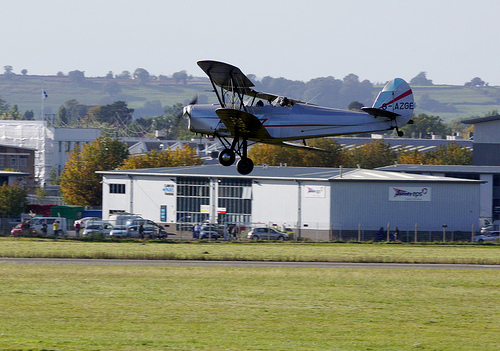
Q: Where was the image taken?
A: It was taken at the field.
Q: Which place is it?
A: It is a field.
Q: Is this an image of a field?
A: Yes, it is showing a field.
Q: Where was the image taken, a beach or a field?
A: It was taken at a field.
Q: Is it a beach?
A: No, it is a field.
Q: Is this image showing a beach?
A: No, the picture is showing a field.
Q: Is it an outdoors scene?
A: Yes, it is outdoors.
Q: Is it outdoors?
A: Yes, it is outdoors.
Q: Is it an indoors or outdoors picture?
A: It is outdoors.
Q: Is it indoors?
A: No, it is outdoors.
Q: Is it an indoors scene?
A: No, it is outdoors.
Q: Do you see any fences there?
A: Yes, there is a fence.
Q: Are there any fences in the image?
A: Yes, there is a fence.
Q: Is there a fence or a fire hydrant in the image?
A: Yes, there is a fence.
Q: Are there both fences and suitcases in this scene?
A: No, there is a fence but no suitcases.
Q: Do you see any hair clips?
A: No, there are no hair clips.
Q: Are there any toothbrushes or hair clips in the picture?
A: No, there are no hair clips or toothbrushes.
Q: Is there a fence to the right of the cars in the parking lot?
A: Yes, there is a fence to the right of the cars.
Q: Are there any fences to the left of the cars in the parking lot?
A: No, the fence is to the right of the cars.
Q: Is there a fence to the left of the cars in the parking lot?
A: No, the fence is to the right of the cars.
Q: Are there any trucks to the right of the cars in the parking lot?
A: No, there is a fence to the right of the cars.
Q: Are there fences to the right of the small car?
A: Yes, there is a fence to the right of the car.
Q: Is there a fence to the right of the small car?
A: Yes, there is a fence to the right of the car.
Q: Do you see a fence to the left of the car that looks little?
A: No, the fence is to the right of the car.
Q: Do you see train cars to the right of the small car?
A: No, there is a fence to the right of the car.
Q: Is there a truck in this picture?
A: No, there are no trucks.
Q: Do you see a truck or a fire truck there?
A: No, there are no trucks or fire trucks.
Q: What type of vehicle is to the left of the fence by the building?
A: The vehicle is a car.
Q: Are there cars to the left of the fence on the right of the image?
A: Yes, there is a car to the left of the fence.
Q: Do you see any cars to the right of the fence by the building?
A: No, the car is to the left of the fence.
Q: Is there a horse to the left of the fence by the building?
A: No, there is a car to the left of the fence.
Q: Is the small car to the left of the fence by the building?
A: Yes, the car is to the left of the fence.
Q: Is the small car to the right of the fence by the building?
A: No, the car is to the left of the fence.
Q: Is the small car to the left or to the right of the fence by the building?
A: The car is to the left of the fence.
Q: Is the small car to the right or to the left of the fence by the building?
A: The car is to the left of the fence.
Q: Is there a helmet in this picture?
A: No, there are no helmets.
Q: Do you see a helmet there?
A: No, there are no helmets.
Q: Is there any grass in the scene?
A: Yes, there is grass.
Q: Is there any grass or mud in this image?
A: Yes, there is grass.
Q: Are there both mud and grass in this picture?
A: No, there is grass but no mud.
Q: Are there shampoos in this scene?
A: No, there are no shampoos.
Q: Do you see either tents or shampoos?
A: No, there are no shampoos or tents.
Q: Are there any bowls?
A: No, there are no bowls.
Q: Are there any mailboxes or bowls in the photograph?
A: No, there are no bowls or mailboxes.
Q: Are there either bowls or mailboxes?
A: No, there are no bowls or mailboxes.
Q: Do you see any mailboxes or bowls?
A: No, there are no bowls or mailboxes.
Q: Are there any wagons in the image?
A: No, there are no wagons.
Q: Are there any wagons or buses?
A: No, there are no wagons or buses.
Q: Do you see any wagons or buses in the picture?
A: No, there are no wagons or buses.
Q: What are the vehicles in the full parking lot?
A: The vehicles are cars.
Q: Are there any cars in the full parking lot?
A: Yes, there are cars in the parking lot.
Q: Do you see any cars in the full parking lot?
A: Yes, there are cars in the parking lot.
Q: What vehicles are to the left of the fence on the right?
A: The vehicles are cars.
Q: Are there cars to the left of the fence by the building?
A: Yes, there are cars to the left of the fence.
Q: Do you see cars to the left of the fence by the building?
A: Yes, there are cars to the left of the fence.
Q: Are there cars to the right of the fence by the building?
A: No, the cars are to the left of the fence.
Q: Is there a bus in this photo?
A: No, there are no buses.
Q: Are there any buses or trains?
A: No, there are no buses or trains.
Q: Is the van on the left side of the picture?
A: Yes, the van is on the left of the image.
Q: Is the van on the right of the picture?
A: No, the van is on the left of the image.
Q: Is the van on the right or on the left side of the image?
A: The van is on the left of the image.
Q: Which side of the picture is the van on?
A: The van is on the left of the image.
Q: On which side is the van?
A: The van is on the left of the image.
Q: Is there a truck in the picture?
A: No, there are no trucks.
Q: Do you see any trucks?
A: No, there are no trucks.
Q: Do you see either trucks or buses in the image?
A: No, there are no trucks or buses.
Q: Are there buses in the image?
A: No, there are no buses.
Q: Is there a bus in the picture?
A: No, there are no buses.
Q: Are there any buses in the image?
A: No, there are no buses.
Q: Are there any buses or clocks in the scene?
A: No, there are no buses or clocks.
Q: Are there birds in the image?
A: No, there are no birds.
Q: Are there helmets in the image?
A: No, there are no helmets.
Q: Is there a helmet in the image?
A: No, there are no helmets.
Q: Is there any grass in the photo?
A: Yes, there is grass.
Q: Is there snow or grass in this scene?
A: Yes, there is grass.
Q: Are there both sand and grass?
A: No, there is grass but no sand.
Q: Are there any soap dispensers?
A: No, there are no soap dispensers.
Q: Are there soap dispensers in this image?
A: No, there are no soap dispensers.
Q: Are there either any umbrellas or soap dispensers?
A: No, there are no soap dispensers or umbrellas.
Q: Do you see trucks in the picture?
A: No, there are no trucks.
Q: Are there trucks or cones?
A: No, there are no trucks or cones.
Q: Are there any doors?
A: Yes, there are doors.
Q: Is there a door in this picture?
A: Yes, there are doors.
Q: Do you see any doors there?
A: Yes, there are doors.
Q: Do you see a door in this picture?
A: Yes, there are doors.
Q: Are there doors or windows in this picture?
A: Yes, there are doors.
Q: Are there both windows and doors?
A: Yes, there are both doors and windows.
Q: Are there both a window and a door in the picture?
A: Yes, there are both a door and a window.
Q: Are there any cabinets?
A: No, there are no cabinets.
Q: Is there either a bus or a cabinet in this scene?
A: No, there are no cabinets or buses.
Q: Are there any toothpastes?
A: No, there are no toothpastes.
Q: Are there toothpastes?
A: No, there are no toothpastes.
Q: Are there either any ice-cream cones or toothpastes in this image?
A: No, there are no toothpastes or ice-cream cones.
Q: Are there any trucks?
A: No, there are no trucks.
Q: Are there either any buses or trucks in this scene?
A: No, there are no trucks or buses.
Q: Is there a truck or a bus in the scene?
A: No, there are no trucks or buses.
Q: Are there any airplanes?
A: Yes, there is an airplane.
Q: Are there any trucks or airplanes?
A: Yes, there is an airplane.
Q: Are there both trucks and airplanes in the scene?
A: No, there is an airplane but no trucks.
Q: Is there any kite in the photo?
A: No, there are no kites.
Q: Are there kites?
A: No, there are no kites.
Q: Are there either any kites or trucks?
A: No, there are no kites or trucks.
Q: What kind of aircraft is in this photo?
A: The aircraft is an airplane.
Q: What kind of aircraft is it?
A: The aircraft is an airplane.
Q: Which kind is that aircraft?
A: This is an airplane.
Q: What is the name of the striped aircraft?
A: The aircraft is an airplane.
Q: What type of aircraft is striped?
A: The aircraft is an airplane.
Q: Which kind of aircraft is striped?
A: The aircraft is an airplane.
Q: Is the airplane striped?
A: Yes, the airplane is striped.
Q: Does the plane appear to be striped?
A: Yes, the plane is striped.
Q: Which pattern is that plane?
A: The plane is striped.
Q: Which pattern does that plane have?
A: The plane has striped pattern.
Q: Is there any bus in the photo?
A: No, there are no buses.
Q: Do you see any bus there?
A: No, there are no buses.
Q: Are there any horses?
A: No, there are no horses.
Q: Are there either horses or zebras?
A: No, there are no horses or zebras.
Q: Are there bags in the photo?
A: No, there are no bags.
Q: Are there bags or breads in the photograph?
A: No, there are no bags or breads.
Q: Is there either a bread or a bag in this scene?
A: No, there are no bags or breads.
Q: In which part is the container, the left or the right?
A: The container is on the left of the image.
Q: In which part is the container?
A: The container is on the left of the image.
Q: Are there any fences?
A: Yes, there is a fence.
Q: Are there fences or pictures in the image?
A: Yes, there is a fence.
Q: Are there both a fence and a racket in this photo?
A: No, there is a fence but no rackets.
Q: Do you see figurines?
A: No, there are no figurines.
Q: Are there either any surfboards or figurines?
A: No, there are no figurines or surfboards.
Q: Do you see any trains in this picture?
A: No, there are no trains.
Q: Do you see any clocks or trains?
A: No, there are no trains or clocks.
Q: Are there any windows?
A: Yes, there are windows.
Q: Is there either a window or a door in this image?
A: Yes, there are windows.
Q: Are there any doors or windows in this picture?
A: Yes, there are windows.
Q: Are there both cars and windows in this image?
A: Yes, there are both windows and a car.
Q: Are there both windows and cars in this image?
A: Yes, there are both windows and a car.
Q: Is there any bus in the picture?
A: No, there are no buses.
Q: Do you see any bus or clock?
A: No, there are no buses or clocks.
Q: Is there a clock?
A: No, there are no clocks.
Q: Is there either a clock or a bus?
A: No, there are no clocks or buses.